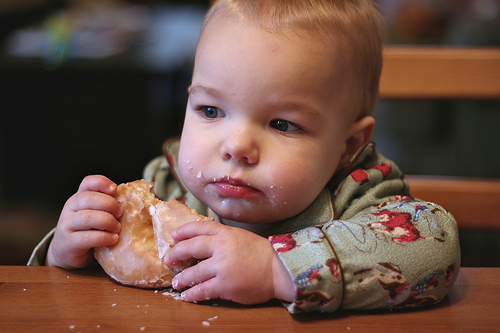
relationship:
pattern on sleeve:
[365, 200, 453, 249] [268, 197, 463, 317]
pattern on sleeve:
[343, 254, 406, 311] [268, 197, 463, 317]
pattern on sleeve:
[287, 252, 341, 319] [268, 197, 463, 317]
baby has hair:
[25, 0, 460, 318] [193, 1, 384, 118]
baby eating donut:
[25, 0, 460, 318] [88, 178, 212, 291]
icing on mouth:
[231, 157, 310, 219] [158, 138, 301, 235]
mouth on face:
[158, 138, 301, 235] [151, 10, 383, 227]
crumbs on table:
[110, 289, 214, 330] [26, 292, 65, 315]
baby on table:
[25, 0, 460, 318] [0, 265, 500, 330]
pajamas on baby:
[23, 145, 465, 317] [25, 0, 460, 318]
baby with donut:
[118, 21, 442, 271] [56, 193, 217, 295]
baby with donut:
[25, 0, 460, 318] [92, 177, 216, 288]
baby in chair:
[25, 0, 460, 318] [371, 43, 496, 227]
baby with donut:
[25, 0, 460, 318] [98, 181, 183, 288]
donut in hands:
[104, 178, 206, 280] [58, 176, 285, 305]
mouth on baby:
[202, 173, 263, 200] [25, 0, 460, 318]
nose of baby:
[219, 117, 258, 163] [25, 0, 460, 318]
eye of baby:
[194, 100, 232, 122] [154, 18, 355, 252]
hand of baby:
[50, 168, 119, 273] [25, 0, 460, 318]